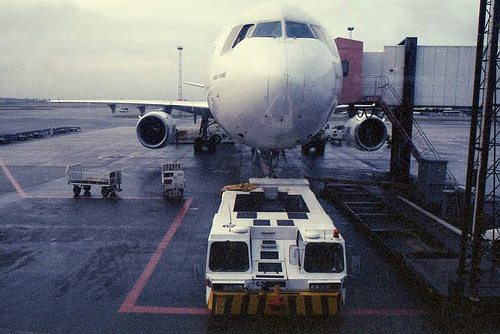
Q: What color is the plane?
A: White.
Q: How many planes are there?
A: One.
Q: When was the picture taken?
A: Daytime.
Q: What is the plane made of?
A: Metal.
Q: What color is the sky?
A: Gray.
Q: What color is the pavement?
A: Black.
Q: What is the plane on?
A: The pavement.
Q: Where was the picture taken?
A: At a airport.